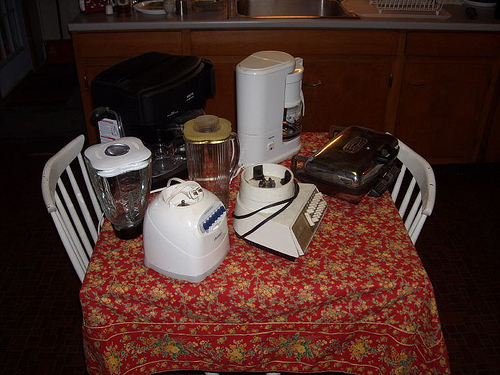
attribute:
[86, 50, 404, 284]
appliances — small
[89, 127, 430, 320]
table — with appliances, with a cloth, has appliances, appliances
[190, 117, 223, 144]
lid — white, yellow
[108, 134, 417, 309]
cloth — red, next to chair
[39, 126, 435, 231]
chair — white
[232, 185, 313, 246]
cord — with appliances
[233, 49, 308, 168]
coffee maker — black, white, an appliance, next to chair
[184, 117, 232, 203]
blender — white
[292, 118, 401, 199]
waffle maker — silver, an appliance, black, white, next to chair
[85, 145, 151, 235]
blender — white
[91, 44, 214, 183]
espresso machine — black, an appliance, white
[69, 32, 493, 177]
door — wooden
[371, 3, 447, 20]
dish stainer — black